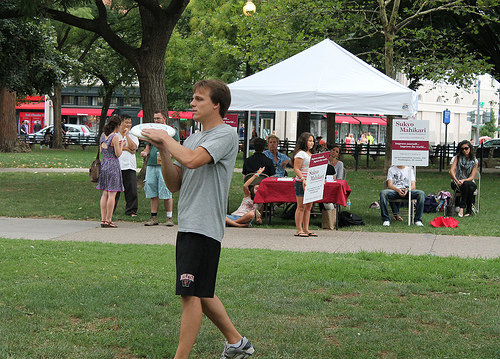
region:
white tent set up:
[235, 31, 463, 177]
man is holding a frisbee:
[111, 111, 184, 159]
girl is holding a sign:
[263, 128, 342, 237]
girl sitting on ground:
[216, 175, 282, 231]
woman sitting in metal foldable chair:
[446, 141, 489, 211]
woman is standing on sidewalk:
[86, 119, 141, 241]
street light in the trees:
[242, 3, 282, 61]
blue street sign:
[433, 102, 459, 170]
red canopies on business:
[327, 115, 397, 137]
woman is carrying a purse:
[84, 137, 104, 183]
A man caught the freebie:
[126, 80, 256, 357]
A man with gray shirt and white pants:
[137, 77, 257, 357]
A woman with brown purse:
[87, 115, 127, 228]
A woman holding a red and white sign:
[292, 131, 333, 237]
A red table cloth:
[253, 176, 351, 211]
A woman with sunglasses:
[449, 139, 483, 217]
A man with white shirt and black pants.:
[112, 110, 140, 220]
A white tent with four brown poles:
[207, 36, 420, 173]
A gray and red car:
[19, 122, 98, 148]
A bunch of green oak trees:
[0, 0, 499, 183]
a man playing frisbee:
[161, 77, 208, 157]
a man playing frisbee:
[80, 52, 227, 336]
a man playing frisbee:
[133, 53, 272, 342]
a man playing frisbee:
[181, 130, 271, 328]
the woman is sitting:
[439, 134, 484, 218]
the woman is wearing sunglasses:
[443, 122, 490, 216]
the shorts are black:
[152, 218, 234, 300]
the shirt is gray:
[164, 120, 239, 248]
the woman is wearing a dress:
[77, 118, 131, 230]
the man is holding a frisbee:
[127, 73, 265, 353]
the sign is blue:
[437, 101, 459, 138]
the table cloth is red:
[262, 174, 288, 202]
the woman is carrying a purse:
[86, 106, 130, 228]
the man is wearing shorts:
[123, 63, 258, 357]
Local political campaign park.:
[227, 64, 430, 234]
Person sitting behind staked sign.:
[382, 160, 432, 230]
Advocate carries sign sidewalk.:
[294, 130, 335, 239]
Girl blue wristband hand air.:
[227, 163, 270, 230]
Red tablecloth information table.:
[251, 158, 366, 226]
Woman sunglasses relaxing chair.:
[448, 135, 485, 225]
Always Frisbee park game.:
[127, 77, 253, 357]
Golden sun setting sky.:
[169, 0, 347, 36]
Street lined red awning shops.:
[17, 83, 229, 153]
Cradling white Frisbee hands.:
[121, 112, 193, 173]